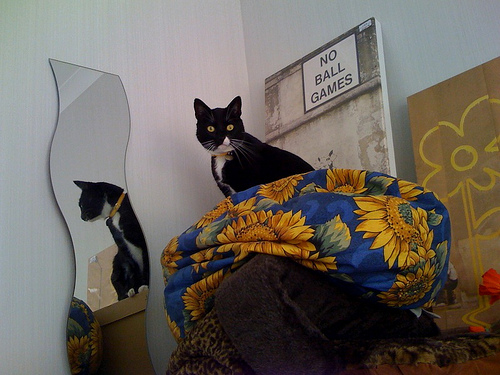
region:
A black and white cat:
[187, 90, 324, 189]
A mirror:
[42, 47, 151, 322]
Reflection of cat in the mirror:
[65, 168, 157, 299]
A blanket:
[156, 167, 458, 298]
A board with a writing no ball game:
[295, 14, 382, 112]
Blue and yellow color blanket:
[152, 166, 464, 345]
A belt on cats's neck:
[65, 177, 128, 229]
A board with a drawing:
[405, 61, 477, 201]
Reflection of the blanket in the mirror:
[56, 295, 101, 372]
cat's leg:
[93, 285, 164, 309]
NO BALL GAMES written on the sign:
[287, 36, 373, 110]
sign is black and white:
[299, 30, 357, 111]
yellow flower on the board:
[407, 78, 497, 317]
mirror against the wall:
[35, 60, 173, 372]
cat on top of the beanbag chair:
[190, 95, 327, 197]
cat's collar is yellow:
[109, 186, 131, 217]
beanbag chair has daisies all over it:
[163, 165, 462, 328]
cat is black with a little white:
[198, 97, 323, 191]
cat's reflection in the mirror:
[75, 170, 149, 310]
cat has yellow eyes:
[198, 119, 247, 133]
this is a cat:
[184, 84, 271, 183]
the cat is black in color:
[247, 145, 275, 177]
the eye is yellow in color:
[224, 120, 238, 133]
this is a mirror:
[73, 77, 121, 288]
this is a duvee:
[288, 172, 386, 273]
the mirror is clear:
[66, 74, 113, 159]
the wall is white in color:
[156, 11, 206, 73]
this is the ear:
[227, 95, 242, 115]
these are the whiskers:
[230, 135, 255, 156]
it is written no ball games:
[306, 45, 351, 103]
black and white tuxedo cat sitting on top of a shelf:
[193, 95, 316, 192]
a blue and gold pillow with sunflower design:
[160, 166, 454, 341]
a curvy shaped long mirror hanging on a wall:
[46, 56, 155, 373]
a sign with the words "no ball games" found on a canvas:
[300, 32, 360, 112]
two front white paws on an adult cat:
[123, 282, 146, 296]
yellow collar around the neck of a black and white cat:
[106, 189, 128, 221]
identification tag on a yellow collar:
[103, 215, 111, 227]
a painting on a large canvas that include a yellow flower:
[406, 54, 499, 333]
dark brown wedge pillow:
[213, 255, 439, 373]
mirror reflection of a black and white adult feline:
[71, 178, 150, 300]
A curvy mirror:
[45, 53, 165, 373]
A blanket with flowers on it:
[160, 169, 457, 345]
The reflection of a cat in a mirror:
[65, 175, 150, 305]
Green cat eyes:
[203, 120, 238, 135]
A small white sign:
[297, 36, 367, 112]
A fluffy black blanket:
[210, 252, 427, 373]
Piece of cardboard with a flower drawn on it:
[408, 51, 499, 296]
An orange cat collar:
[100, 186, 132, 224]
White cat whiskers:
[195, 136, 254, 159]